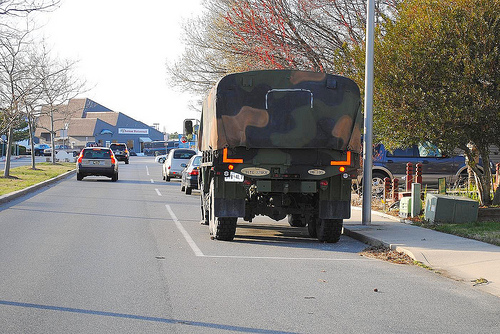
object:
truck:
[192, 68, 363, 247]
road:
[0, 155, 499, 333]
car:
[180, 155, 203, 195]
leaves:
[380, 250, 394, 257]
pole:
[360, 0, 377, 226]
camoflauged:
[198, 68, 365, 152]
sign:
[177, 133, 197, 149]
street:
[0, 147, 500, 332]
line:
[153, 187, 164, 198]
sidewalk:
[336, 204, 500, 283]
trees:
[15, 36, 97, 173]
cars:
[74, 147, 117, 182]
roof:
[32, 97, 168, 139]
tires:
[206, 177, 240, 243]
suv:
[353, 129, 488, 197]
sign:
[115, 127, 151, 136]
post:
[166, 127, 204, 154]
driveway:
[346, 132, 497, 197]